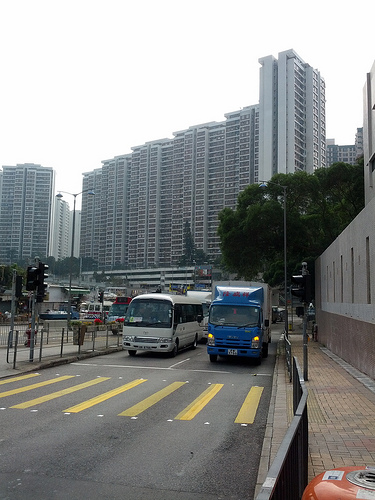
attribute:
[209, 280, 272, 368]
truck — blue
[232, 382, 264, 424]
line — yellow, painted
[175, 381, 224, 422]
line — yellow, painted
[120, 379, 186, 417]
line — yellow, painted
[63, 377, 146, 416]
line — yellow, painted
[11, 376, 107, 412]
line — yellow, painted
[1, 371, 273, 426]
walkway — for pedestrians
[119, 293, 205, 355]
bus — white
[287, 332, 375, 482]
sidewalk — brick, bricked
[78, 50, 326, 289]
building — large, white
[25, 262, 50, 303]
traffic light — black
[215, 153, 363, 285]
trees — green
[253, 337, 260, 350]
headlight — on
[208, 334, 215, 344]
headlight — on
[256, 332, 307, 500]
barrier — metal, black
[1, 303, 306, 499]
road — paved, tarmac